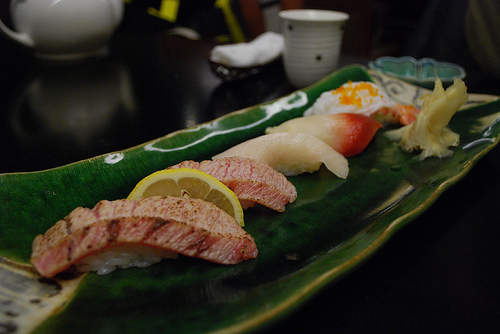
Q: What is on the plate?
A: Fish.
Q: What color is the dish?
A: Green.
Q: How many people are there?
A: 0.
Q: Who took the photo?
A: Chef.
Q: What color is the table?
A: Black.